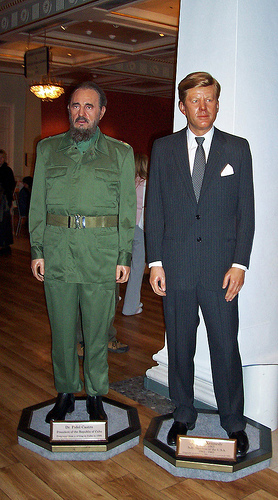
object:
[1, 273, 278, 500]
floor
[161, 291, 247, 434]
trouser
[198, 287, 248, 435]
leg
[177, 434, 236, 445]
edge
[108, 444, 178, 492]
board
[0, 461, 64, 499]
board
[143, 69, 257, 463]
statue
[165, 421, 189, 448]
shoe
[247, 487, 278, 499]
board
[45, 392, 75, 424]
boot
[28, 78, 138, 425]
figure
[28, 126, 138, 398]
uniform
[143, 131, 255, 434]
suit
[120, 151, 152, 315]
woman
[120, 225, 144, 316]
jeans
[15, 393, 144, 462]
base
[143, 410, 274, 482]
base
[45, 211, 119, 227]
belt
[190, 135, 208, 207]
tie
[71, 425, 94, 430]
writing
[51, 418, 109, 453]
plate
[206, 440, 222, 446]
writing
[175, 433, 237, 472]
plate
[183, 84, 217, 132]
face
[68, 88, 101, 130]
face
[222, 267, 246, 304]
hand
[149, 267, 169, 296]
hand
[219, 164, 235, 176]
handkerchief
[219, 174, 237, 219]
pocket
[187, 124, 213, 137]
neck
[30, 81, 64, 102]
light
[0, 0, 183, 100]
ceiling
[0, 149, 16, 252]
person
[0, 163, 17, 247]
clothes